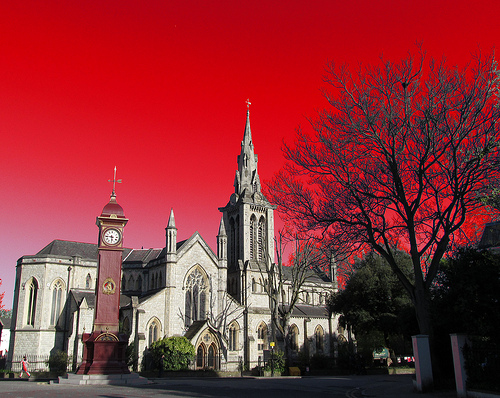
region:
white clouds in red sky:
[32, 21, 98, 76]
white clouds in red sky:
[212, 51, 269, 93]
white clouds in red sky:
[101, 85, 141, 110]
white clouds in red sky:
[88, 128, 171, 162]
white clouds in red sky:
[178, 147, 212, 189]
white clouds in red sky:
[67, 143, 94, 158]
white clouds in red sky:
[212, 12, 278, 37]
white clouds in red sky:
[69, 29, 135, 97]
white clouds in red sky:
[103, 119, 150, 153]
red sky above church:
[0, 5, 499, 248]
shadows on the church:
[52, 288, 356, 376]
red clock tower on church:
[91, 164, 123, 364]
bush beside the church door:
[151, 333, 193, 370]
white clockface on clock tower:
[100, 230, 120, 243]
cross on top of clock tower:
[102, 165, 121, 196]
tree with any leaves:
[262, 52, 493, 387]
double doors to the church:
[196, 341, 220, 372]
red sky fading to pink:
[6, 155, 473, 307]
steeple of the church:
[237, 91, 259, 200]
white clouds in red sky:
[197, 50, 207, 67]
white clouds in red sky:
[164, 109, 191, 133]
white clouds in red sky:
[74, 89, 128, 160]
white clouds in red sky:
[331, 29, 373, 49]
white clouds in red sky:
[219, 67, 276, 88]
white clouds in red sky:
[156, 49, 194, 100]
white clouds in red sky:
[33, 101, 90, 166]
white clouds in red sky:
[100, 34, 158, 96]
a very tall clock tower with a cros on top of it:
[76, 159, 133, 381]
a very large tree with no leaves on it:
[298, 83, 496, 380]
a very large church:
[0, 96, 364, 378]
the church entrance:
[191, 328, 230, 375]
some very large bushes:
[143, 326, 192, 374]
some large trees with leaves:
[332, 240, 433, 378]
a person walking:
[11, 345, 41, 387]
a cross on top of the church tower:
[239, 93, 264, 112]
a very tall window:
[46, 271, 68, 331]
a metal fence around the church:
[2, 350, 72, 377]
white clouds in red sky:
[3, 16, 45, 82]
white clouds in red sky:
[74, 69, 157, 149]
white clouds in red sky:
[5, 91, 51, 155]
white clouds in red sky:
[237, 18, 288, 76]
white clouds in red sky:
[323, 19, 373, 56]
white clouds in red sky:
[30, 77, 115, 150]